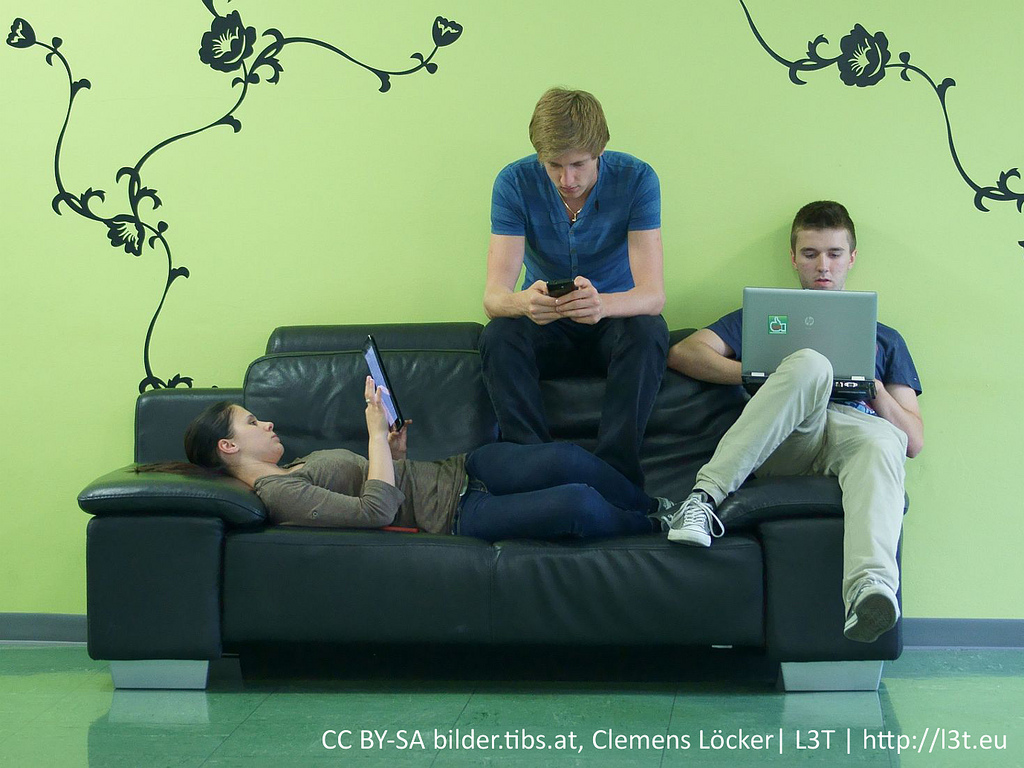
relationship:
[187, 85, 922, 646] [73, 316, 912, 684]
people on sofa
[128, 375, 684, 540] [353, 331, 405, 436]
people on gadget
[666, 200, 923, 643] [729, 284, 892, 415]
man on gadget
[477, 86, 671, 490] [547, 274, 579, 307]
man on gadget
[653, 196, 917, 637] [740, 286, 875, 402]
man on gadget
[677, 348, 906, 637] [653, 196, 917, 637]
pants on man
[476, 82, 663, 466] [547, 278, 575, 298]
man looks at gadget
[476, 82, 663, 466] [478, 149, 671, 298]
man wears shirt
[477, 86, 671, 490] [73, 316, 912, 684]
man on sofa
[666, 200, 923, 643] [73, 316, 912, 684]
man on sofa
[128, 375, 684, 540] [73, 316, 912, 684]
people on sofa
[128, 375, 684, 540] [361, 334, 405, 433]
people holds gadget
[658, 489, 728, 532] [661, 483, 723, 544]
shoelace on shoe